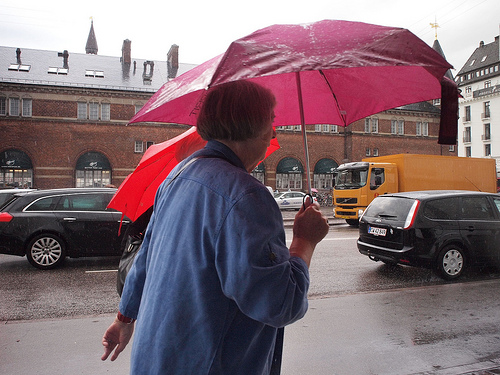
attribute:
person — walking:
[103, 78, 330, 374]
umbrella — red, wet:
[123, 20, 465, 127]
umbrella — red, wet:
[104, 123, 281, 235]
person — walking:
[115, 204, 155, 297]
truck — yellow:
[330, 153, 498, 227]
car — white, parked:
[271, 188, 319, 210]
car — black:
[0, 187, 144, 271]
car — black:
[357, 190, 499, 282]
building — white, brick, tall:
[454, 34, 499, 186]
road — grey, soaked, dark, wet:
[1, 222, 497, 324]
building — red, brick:
[1, 44, 457, 196]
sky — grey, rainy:
[1, 1, 499, 74]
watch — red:
[115, 310, 135, 326]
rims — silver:
[29, 235, 62, 266]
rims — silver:
[442, 249, 465, 275]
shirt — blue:
[116, 138, 310, 374]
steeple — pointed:
[84, 19, 99, 55]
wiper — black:
[377, 212, 396, 220]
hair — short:
[196, 79, 276, 141]